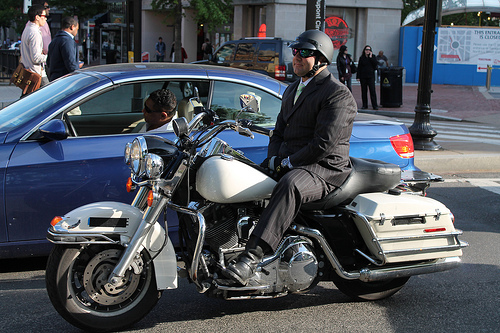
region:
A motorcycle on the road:
[46, 117, 463, 311]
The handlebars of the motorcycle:
[173, 103, 271, 144]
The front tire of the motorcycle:
[52, 223, 158, 323]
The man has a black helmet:
[293, 27, 336, 59]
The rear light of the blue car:
[390, 133, 417, 156]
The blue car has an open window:
[66, 63, 207, 131]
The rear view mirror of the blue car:
[41, 115, 75, 141]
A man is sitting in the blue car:
[146, 91, 177, 128]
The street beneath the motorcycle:
[323, 298, 493, 327]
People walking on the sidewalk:
[21, 5, 78, 77]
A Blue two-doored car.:
[0, 60, 425, 265]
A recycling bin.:
[377, 65, 403, 106]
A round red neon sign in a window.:
[323, 14, 352, 47]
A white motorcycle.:
[43, 90, 470, 329]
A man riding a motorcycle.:
[44, 32, 469, 331]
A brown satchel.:
[12, 54, 56, 94]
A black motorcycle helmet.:
[290, 26, 337, 64]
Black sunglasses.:
[290, 45, 318, 58]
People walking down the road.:
[12, 0, 90, 109]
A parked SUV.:
[183, 38, 305, 82]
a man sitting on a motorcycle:
[222, 25, 354, 293]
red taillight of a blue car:
[391, 130, 414, 159]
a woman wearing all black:
[357, 43, 380, 107]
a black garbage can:
[377, 64, 405, 109]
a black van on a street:
[193, 34, 297, 83]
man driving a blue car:
[137, 87, 181, 132]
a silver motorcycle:
[40, 99, 467, 321]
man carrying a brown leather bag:
[8, 63, 41, 94]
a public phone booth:
[98, 24, 128, 63]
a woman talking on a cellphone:
[361, 44, 375, 63]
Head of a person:
[280, 24, 332, 74]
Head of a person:
[361, 41, 373, 58]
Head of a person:
[329, 43, 351, 56]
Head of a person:
[54, 13, 84, 38]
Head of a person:
[29, 5, 51, 23]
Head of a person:
[151, 33, 168, 45]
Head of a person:
[169, 35, 185, 49]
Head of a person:
[136, 88, 187, 123]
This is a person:
[226, 24, 356, 301]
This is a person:
[113, 79, 185, 165]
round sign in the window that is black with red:
[321, 15, 348, 50]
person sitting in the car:
[141, 89, 179, 133]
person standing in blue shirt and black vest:
[153, 35, 166, 61]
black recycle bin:
[377, 66, 404, 111]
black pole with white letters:
[303, 1, 325, 30]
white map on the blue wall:
[436, 27, 498, 66]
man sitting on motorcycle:
[223, 32, 350, 288]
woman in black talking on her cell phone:
[355, 45, 382, 112]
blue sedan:
[1, 62, 416, 272]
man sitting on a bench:
[373, 49, 391, 81]